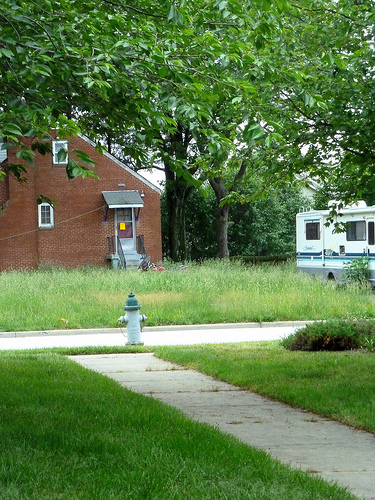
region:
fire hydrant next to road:
[116, 290, 146, 346]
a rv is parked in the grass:
[293, 196, 370, 279]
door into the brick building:
[112, 205, 132, 250]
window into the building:
[38, 197, 52, 227]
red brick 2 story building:
[0, 110, 160, 263]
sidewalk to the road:
[60, 349, 368, 493]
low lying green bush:
[279, 317, 369, 349]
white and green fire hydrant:
[116, 290, 146, 346]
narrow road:
[0, 318, 309, 348]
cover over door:
[99, 187, 142, 225]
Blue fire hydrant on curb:
[109, 290, 155, 352]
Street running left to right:
[0, 312, 373, 360]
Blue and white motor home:
[286, 205, 374, 285]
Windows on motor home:
[300, 219, 373, 241]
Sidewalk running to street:
[62, 350, 371, 491]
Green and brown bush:
[276, 314, 371, 359]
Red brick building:
[1, 92, 170, 280]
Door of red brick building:
[96, 186, 152, 272]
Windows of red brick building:
[32, 138, 73, 231]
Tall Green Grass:
[1, 270, 368, 323]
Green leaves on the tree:
[165, 29, 227, 105]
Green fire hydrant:
[113, 293, 150, 342]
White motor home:
[293, 198, 374, 277]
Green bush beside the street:
[289, 311, 365, 354]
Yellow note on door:
[117, 219, 128, 231]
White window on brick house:
[34, 198, 58, 231]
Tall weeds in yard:
[193, 261, 228, 301]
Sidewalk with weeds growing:
[66, 348, 198, 376]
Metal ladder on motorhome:
[294, 201, 311, 215]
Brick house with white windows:
[0, 118, 170, 277]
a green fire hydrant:
[115, 289, 149, 347]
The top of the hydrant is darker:
[121, 290, 139, 310]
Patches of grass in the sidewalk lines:
[90, 358, 320, 425]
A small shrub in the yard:
[279, 320, 371, 351]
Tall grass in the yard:
[0, 261, 114, 328]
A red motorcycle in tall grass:
[135, 254, 188, 275]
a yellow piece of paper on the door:
[118, 220, 126, 231]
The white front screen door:
[113, 204, 134, 250]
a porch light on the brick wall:
[140, 188, 145, 198]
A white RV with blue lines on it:
[291, 200, 374, 294]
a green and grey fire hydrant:
[119, 295, 146, 345]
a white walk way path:
[143, 354, 186, 405]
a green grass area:
[43, 365, 110, 467]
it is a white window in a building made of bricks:
[37, 202, 57, 229]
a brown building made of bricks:
[60, 194, 97, 250]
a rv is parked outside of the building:
[289, 215, 374, 278]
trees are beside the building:
[160, 57, 237, 252]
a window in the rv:
[305, 221, 321, 241]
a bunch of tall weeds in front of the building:
[29, 273, 99, 320]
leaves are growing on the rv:
[343, 261, 367, 282]